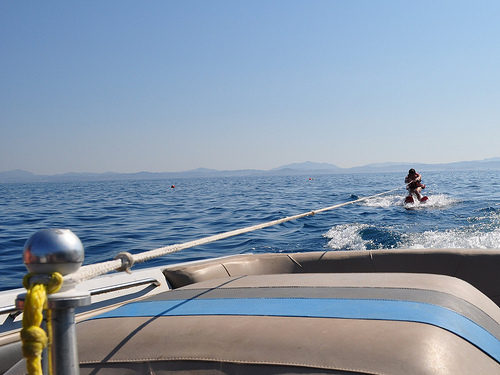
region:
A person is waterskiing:
[400, 165, 432, 208]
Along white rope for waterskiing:
[67, 179, 414, 287]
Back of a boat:
[1, 245, 498, 371]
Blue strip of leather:
[95, 295, 499, 353]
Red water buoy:
[167, 180, 178, 190]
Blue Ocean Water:
[13, 190, 139, 225]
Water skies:
[401, 196, 433, 204]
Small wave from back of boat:
[320, 220, 496, 261]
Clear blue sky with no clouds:
[0, 0, 490, 137]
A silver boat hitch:
[17, 225, 102, 315]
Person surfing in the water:
[394, 159, 436, 212]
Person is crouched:
[391, 161, 439, 210]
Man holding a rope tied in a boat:
[11, 155, 433, 321]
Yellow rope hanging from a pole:
[6, 265, 66, 371]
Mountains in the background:
[1, 147, 496, 173]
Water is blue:
[0, 165, 490, 255]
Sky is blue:
[5, 1, 495, 161]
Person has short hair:
[394, 156, 439, 211]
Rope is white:
[24, 174, 419, 291]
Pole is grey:
[45, 311, 85, 373]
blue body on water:
[72, 195, 163, 233]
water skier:
[357, 163, 462, 253]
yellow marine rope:
[10, 260, 68, 372]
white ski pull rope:
[73, 155, 442, 297]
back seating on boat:
[202, 239, 494, 315]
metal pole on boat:
[9, 216, 121, 373]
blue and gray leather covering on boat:
[117, 288, 497, 374]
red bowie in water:
[157, 177, 199, 202]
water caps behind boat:
[335, 213, 496, 247]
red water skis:
[402, 189, 437, 213]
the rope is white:
[103, 255, 158, 277]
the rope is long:
[52, 152, 475, 287]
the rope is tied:
[19, 277, 69, 373]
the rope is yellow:
[5, 261, 62, 371]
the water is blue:
[24, 179, 163, 225]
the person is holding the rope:
[390, 165, 445, 212]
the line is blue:
[142, 294, 446, 351]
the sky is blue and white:
[90, 96, 242, 173]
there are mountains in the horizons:
[90, 152, 336, 183]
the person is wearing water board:
[390, 159, 445, 215]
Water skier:
[388, 162, 435, 211]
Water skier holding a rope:
[7, 165, 442, 301]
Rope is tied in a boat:
[1, 211, 116, 335]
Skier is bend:
[394, 159, 439, 216]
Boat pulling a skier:
[0, 219, 497, 373]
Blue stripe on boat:
[96, 288, 498, 355]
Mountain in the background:
[3, 143, 498, 181]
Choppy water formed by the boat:
[314, 216, 498, 248]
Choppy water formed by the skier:
[353, 188, 453, 210]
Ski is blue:
[6, 0, 494, 155]